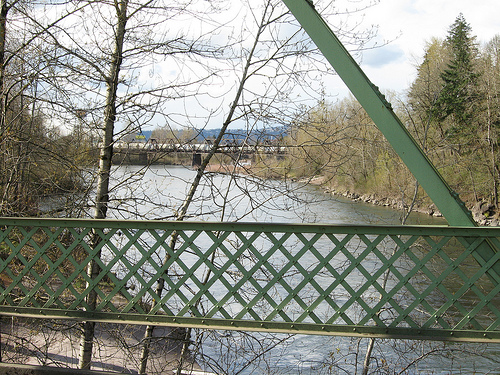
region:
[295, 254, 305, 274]
THE FENCE IS GREEN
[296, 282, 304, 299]
THE FENCE IS GREEN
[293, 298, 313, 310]
THE FENCE IS GREEN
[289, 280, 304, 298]
THE FENCE IS GREEN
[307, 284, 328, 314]
THE FENCE IS GREEN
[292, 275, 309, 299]
THE FENCE IS GREEN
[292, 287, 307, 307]
THE FENCE IS GREEN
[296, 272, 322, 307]
THE FENCE IS GREEN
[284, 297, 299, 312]
THE FENCE IS GREEN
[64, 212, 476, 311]
green metal fence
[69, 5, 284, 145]
brown dry trees without leaves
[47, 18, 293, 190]
trees behind fence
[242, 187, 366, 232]
calm blue river water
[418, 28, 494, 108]
tall green pine tree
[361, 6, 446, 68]
white fluffy clouds in the sky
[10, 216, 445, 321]
fence made of green metal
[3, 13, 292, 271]
two brown trees behind fence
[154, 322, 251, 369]
brown river bank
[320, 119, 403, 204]
trees next to blue river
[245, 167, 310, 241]
The water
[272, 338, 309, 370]
The water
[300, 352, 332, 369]
The water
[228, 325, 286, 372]
The water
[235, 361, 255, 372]
The water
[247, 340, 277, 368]
The water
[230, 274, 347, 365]
The water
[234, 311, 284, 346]
The water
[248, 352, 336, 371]
The water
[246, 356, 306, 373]
The water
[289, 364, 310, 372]
The water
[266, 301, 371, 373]
The water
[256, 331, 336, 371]
The water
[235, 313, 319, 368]
The water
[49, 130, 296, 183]
There's a bridge over water.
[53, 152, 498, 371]
The water is ripply.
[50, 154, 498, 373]
The water is wavy.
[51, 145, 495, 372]
The water is moving swiftly.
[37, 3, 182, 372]
The tree is bare.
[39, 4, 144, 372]
The tree is leafless.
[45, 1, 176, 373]
The tree is leaning.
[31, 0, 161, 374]
The tree is barren.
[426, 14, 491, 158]
The pine tree is green.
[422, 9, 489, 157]
The pine tree is living.